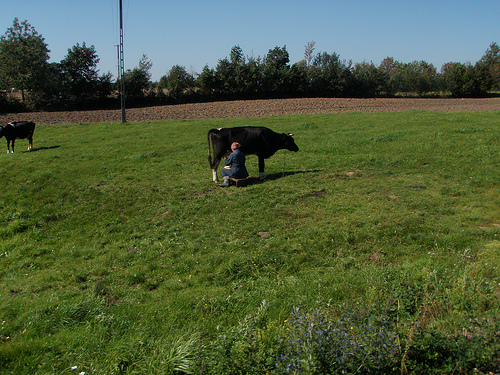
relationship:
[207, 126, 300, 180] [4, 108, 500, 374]
cow in grass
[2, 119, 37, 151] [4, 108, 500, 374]
cow in grass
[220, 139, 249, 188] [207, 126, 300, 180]
person milking cow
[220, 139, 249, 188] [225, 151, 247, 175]
person wears jacket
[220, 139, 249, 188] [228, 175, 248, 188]
person on stool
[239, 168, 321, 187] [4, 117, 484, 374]
shadow on grass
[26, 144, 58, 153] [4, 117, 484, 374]
shadow on grass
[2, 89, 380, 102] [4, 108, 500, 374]
fence near grass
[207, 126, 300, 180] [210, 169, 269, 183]
cow has feet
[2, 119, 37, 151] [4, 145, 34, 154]
cow has feet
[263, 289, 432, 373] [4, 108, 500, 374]
flowers in grass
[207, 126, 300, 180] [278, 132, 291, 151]
cow has neck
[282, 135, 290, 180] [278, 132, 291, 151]
rope on neck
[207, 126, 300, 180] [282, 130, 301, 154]
cow has head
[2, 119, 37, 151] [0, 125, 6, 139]
cow has head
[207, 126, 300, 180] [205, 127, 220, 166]
cow has tail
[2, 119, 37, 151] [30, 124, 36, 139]
cow has tail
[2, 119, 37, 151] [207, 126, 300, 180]
cow behind cow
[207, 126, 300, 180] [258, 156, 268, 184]
cow has legs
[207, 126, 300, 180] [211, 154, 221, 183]
cow has legs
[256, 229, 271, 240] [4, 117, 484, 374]
spot on grass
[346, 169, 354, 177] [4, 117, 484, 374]
spot on grass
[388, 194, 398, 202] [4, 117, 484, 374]
spot on grass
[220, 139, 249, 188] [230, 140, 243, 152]
person has hat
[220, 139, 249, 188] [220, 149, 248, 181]
person has clothing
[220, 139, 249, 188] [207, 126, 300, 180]
person owns cow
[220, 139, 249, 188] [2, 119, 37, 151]
person owns cow